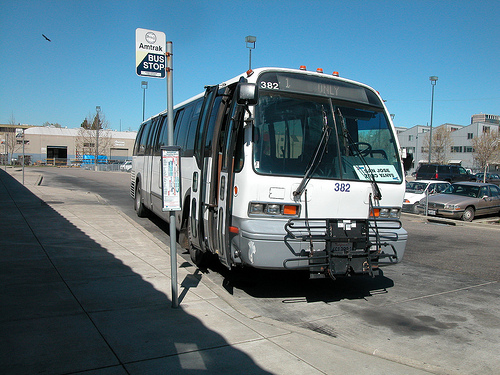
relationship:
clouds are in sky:
[406, 110, 424, 119] [60, 4, 478, 28]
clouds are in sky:
[113, 116, 129, 126] [324, 12, 437, 44]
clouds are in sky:
[458, 93, 471, 107] [287, 13, 460, 55]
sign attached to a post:
[127, 20, 170, 90] [156, 82, 206, 323]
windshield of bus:
[258, 95, 401, 185] [108, 48, 428, 309]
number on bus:
[325, 177, 357, 193] [119, 35, 433, 324]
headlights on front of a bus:
[245, 204, 399, 227] [128, 68, 435, 318]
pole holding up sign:
[150, 42, 190, 307] [124, 18, 174, 81]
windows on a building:
[447, 137, 472, 160] [430, 108, 491, 166]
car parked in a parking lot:
[416, 170, 490, 224] [379, 140, 499, 263]